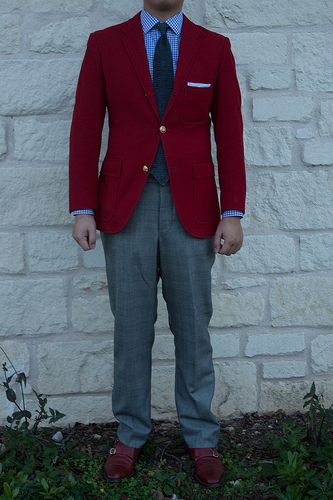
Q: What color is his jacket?
A: Red.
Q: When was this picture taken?
A: Daytime.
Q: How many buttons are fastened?
A: 1.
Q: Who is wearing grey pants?
A: Man in photo.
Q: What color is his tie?
A: Navy Blue.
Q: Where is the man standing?
A: In front of a wall.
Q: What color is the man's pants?
A: Grey.